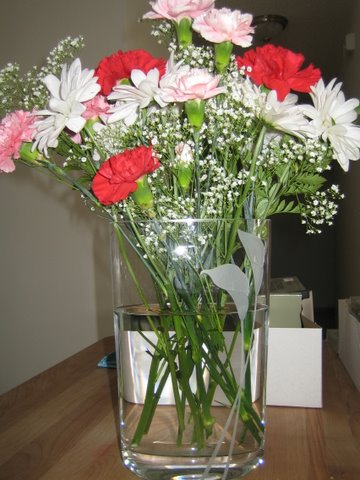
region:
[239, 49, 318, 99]
The flower is red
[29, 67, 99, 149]
The flower is white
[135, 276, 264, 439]
The stems are green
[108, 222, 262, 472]
The vase has half empty water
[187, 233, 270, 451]
There's white design on the vase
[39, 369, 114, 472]
The wood is brown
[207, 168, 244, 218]
The small flowers are white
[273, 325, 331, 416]
There's a white box behind the vase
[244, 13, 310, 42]
The light on the ceiling is off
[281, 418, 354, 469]
The desk has lines.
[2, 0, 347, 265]
A nice flower arrangement.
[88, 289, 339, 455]
a glass vase with water in it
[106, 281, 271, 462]
water inside of a vase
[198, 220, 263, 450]
two lilies etched onto the vase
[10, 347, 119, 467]
wooden counter top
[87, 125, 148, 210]
red carnation flower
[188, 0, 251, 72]
pink carnation flower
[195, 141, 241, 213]
white baby's breath flowers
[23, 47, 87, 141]
one white daisy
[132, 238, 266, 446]
green flower stems inside the vase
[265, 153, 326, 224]
green fern leaves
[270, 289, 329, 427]
white cardboard box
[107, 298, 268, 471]
Clear water filling vase.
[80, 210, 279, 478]
Crystal vase with etching in the side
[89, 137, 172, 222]
Bloom of red carnation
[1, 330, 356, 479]
Wooden surface with items resting on it.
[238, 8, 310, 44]
Dome shaped light fixture on the ceiling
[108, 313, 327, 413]
Bottom of a thin cardboard box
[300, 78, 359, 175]
White daisy with green center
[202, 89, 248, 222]
Bunch of baby's breath.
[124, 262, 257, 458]
Green flower stems submerged in water.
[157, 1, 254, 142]
Three pink carnations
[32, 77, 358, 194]
Baby's-breath, daisies and carnations.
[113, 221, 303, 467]
Tall, clear glass vase with water.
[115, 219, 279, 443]
Tall, green stems of flowers.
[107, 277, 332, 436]
White, cardboard box, bottom.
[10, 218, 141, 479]
A white wall and a wooden floor.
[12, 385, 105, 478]
Wood floor, arranged in light-colored, stripes.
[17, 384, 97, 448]
Wood-grain, showing curving patterns, distinct in shade from background.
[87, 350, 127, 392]
A blue corner section of fabric, probably a rug.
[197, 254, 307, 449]
Stenciled design, resembling graceful leaves with crossed stems.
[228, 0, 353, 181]
Dark passageway, with unlit, circular light fixture on ceiling.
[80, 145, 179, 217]
A red flower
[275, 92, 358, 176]
White flowers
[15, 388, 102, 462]
The table is wooden and light brown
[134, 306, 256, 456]
Flower stems in a vase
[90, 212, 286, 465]
A clear glass vase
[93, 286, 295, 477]
Water inside the vase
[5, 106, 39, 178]
A pink flower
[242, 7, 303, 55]
A light on the ceiling is not on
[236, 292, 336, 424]
A white box is behind a vase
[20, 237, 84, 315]
The wall is white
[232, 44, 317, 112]
A red flower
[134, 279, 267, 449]
Stems of the flowers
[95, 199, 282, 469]
A clear flower vase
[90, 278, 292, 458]
Water is the flower vase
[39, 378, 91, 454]
A brown wooden table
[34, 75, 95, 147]
A white flower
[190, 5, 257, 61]
The flower is light pink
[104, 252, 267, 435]
Flower stems are green